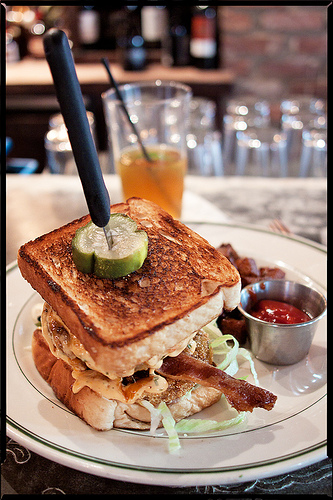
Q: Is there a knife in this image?
A: Yes, there is a knife.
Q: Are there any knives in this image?
A: Yes, there is a knife.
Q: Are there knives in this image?
A: Yes, there is a knife.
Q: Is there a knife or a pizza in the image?
A: Yes, there is a knife.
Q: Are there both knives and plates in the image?
A: Yes, there are both a knife and plates.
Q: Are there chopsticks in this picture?
A: No, there are no chopsticks.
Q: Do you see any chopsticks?
A: No, there are no chopsticks.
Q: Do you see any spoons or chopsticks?
A: No, there are no chopsticks or spoons.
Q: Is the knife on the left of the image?
A: Yes, the knife is on the left of the image.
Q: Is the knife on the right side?
A: No, the knife is on the left of the image.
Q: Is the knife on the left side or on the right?
A: The knife is on the left of the image.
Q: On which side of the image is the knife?
A: The knife is on the left of the image.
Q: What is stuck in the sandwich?
A: The knife is stuck in the sandwich.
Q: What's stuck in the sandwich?
A: The knife is stuck in the sandwich.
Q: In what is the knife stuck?
A: The knife is stuck in the sandwich.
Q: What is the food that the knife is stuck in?
A: The food is a sandwich.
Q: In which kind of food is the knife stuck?
A: The knife is stuck in the sandwich.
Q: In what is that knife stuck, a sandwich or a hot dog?
A: The knife is stuck in a sandwich.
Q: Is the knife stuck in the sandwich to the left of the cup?
A: Yes, the knife is stuck in the sandwich.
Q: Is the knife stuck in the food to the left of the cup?
A: Yes, the knife is stuck in the sandwich.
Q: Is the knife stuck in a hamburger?
A: No, the knife is stuck in the sandwich.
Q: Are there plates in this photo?
A: Yes, there is a plate.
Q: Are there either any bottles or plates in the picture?
A: Yes, there is a plate.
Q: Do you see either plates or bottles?
A: Yes, there is a plate.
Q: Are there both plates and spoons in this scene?
A: No, there is a plate but no spoons.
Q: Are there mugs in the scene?
A: No, there are no mugs.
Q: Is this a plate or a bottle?
A: This is a plate.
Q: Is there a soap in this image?
A: No, there are no soaps.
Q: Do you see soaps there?
A: No, there are no soaps.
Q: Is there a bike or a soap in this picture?
A: No, there are no soaps or bikes.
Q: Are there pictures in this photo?
A: No, there are no pictures.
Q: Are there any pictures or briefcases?
A: No, there are no pictures or briefcases.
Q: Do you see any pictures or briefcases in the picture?
A: No, there are no pictures or briefcases.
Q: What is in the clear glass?
A: The liquid is in the glass.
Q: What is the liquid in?
A: The liquid is in the glass.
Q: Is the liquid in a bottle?
A: No, the liquid is in the glass.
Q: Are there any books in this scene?
A: No, there are no books.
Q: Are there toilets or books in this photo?
A: No, there are no books or toilets.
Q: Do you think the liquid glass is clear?
A: Yes, the glass is clear.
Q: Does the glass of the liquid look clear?
A: Yes, the glass is clear.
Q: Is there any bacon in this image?
A: Yes, there is bacon.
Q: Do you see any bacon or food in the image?
A: Yes, there is bacon.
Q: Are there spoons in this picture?
A: No, there are no spoons.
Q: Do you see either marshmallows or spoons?
A: No, there are no spoons or marshmallows.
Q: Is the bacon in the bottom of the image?
A: Yes, the bacon is in the bottom of the image.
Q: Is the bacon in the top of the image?
A: No, the bacon is in the bottom of the image.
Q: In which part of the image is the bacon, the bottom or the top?
A: The bacon is in the bottom of the image.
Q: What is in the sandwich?
A: The bacon is in the sandwich.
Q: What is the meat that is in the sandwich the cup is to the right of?
A: The meat is bacon.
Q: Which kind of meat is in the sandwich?
A: The meat is bacon.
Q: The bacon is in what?
A: The bacon is in the sandwich.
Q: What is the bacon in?
A: The bacon is in the sandwich.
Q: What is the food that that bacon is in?
A: The food is a sandwich.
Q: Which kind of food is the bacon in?
A: The bacon is in the sandwich.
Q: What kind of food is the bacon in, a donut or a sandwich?
A: The bacon is in a sandwich.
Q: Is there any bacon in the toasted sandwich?
A: Yes, there is bacon in the sandwich.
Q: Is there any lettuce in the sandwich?
A: No, there is bacon in the sandwich.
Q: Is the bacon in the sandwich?
A: Yes, the bacon is in the sandwich.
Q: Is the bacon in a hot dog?
A: No, the bacon is in the sandwich.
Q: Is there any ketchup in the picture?
A: Yes, there is ketchup.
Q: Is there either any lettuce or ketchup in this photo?
A: Yes, there is ketchup.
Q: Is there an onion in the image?
A: No, there are no onions.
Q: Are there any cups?
A: Yes, there is a cup.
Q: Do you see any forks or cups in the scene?
A: Yes, there is a cup.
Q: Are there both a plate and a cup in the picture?
A: Yes, there are both a cup and a plate.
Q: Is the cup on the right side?
A: Yes, the cup is on the right of the image.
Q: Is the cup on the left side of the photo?
A: No, the cup is on the right of the image.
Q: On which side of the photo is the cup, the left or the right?
A: The cup is on the right of the image.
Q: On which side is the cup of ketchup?
A: The cup is on the right of the image.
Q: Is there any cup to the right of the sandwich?
A: Yes, there is a cup to the right of the sandwich.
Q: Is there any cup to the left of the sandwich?
A: No, the cup is to the right of the sandwich.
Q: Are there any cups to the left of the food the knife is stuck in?
A: No, the cup is to the right of the sandwich.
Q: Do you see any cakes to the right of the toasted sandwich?
A: No, there is a cup to the right of the sandwich.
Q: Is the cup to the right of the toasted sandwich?
A: Yes, the cup is to the right of the sandwich.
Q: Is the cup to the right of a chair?
A: No, the cup is to the right of the sandwich.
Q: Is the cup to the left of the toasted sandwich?
A: No, the cup is to the right of the sandwich.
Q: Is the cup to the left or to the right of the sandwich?
A: The cup is to the right of the sandwich.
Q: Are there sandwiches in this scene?
A: Yes, there is a sandwich.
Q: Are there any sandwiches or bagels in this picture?
A: Yes, there is a sandwich.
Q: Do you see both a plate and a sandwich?
A: Yes, there are both a sandwich and a plate.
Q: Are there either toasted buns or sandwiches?
A: Yes, there is a toasted sandwich.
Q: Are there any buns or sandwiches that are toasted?
A: Yes, the sandwich is toasted.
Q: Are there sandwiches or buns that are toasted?
A: Yes, the sandwich is toasted.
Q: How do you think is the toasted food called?
A: The food is a sandwich.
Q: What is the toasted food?
A: The food is a sandwich.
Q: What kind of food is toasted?
A: The food is a sandwich.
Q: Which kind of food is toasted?
A: The food is a sandwich.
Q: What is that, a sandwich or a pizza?
A: That is a sandwich.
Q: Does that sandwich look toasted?
A: Yes, the sandwich is toasted.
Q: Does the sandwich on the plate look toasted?
A: Yes, the sandwich is toasted.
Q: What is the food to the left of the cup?
A: The food is a sandwich.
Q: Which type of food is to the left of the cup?
A: The food is a sandwich.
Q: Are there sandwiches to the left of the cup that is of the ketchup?
A: Yes, there is a sandwich to the left of the cup.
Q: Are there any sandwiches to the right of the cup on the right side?
A: No, the sandwich is to the left of the cup.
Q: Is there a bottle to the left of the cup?
A: No, there is a sandwich to the left of the cup.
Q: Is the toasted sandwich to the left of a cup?
A: Yes, the sandwich is to the left of a cup.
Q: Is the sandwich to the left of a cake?
A: No, the sandwich is to the left of a cup.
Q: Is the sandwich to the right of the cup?
A: No, the sandwich is to the left of the cup.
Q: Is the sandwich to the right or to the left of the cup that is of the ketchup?
A: The sandwich is to the left of the cup.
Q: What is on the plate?
A: The sandwich is on the plate.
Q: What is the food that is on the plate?
A: The food is a sandwich.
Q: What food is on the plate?
A: The food is a sandwich.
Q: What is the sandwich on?
A: The sandwich is on the plate.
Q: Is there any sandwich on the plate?
A: Yes, there is a sandwich on the plate.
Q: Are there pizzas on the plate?
A: No, there is a sandwich on the plate.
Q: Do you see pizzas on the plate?
A: No, there is a sandwich on the plate.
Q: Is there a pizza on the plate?
A: No, there is a sandwich on the plate.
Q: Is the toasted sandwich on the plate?
A: Yes, the sandwich is on the plate.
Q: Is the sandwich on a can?
A: No, the sandwich is on the plate.